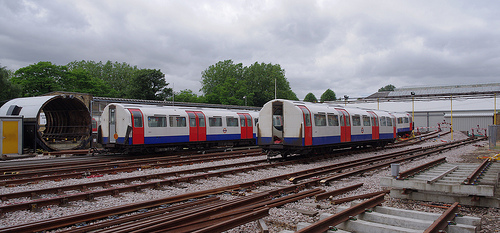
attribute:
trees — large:
[198, 59, 296, 113]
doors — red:
[190, 106, 209, 143]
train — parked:
[255, 100, 412, 157]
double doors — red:
[186, 110, 208, 142]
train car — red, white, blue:
[260, 97, 417, 151]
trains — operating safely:
[94, 91, 414, 153]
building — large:
[362, 87, 498, 104]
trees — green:
[201, 65, 300, 115]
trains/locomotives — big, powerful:
[97, 97, 415, 154]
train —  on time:
[252, 92, 454, 126]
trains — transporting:
[56, 67, 481, 202]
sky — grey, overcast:
[0, 0, 498, 102]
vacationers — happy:
[317, 117, 337, 126]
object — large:
[4, 83, 103, 167]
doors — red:
[298, 122, 400, 142]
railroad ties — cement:
[329, 202, 444, 228]